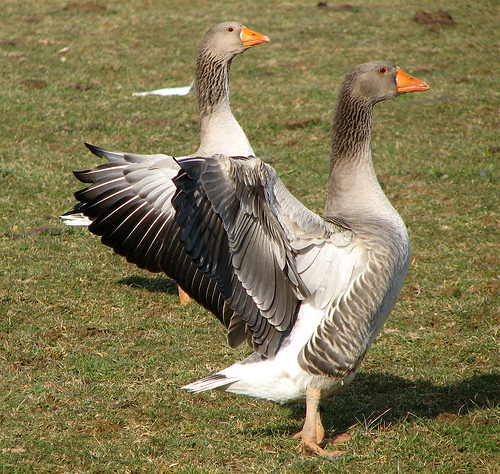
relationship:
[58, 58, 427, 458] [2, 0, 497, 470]
bird in grass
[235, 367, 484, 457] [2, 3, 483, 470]
shadow on ground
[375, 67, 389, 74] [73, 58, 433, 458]
eye of goose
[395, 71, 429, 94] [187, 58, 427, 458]
beak of bird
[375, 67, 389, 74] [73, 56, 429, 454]
eye of bird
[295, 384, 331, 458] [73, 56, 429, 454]
leg of bird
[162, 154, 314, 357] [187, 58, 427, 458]
wing of bird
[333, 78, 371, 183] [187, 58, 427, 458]
neck of bird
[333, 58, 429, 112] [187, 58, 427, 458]
head of bird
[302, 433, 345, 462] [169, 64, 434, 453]
claw of bird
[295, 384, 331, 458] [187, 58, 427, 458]
leg of bird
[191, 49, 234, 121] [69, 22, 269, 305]
neck of bird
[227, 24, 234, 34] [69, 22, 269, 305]
eye of bird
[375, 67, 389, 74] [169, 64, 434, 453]
eye of bird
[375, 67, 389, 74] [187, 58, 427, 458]
eye of bird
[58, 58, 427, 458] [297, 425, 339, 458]
bird has foot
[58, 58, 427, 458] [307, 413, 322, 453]
bird has foot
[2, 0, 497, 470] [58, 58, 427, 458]
grass by bird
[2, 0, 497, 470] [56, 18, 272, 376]
grass by goose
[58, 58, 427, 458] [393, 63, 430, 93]
bird has beak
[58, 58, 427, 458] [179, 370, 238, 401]
bird has tail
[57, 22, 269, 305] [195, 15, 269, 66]
bird has head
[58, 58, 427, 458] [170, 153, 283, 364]
bird has wing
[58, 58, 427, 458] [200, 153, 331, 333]
bird has wing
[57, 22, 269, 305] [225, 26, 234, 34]
bird has eye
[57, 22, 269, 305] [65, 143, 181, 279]
bird has feathers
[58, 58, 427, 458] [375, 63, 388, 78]
bird has eye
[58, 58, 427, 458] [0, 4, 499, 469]
bird on lawn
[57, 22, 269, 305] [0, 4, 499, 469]
bird on lawn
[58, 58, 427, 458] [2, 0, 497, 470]
bird standing on grass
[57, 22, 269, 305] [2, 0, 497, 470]
bird standing on grass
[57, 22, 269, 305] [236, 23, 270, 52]
bird has beak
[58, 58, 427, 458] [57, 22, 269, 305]
bird standing by bird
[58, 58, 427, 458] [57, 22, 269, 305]
bird standing next to bird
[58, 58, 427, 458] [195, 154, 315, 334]
bird has wing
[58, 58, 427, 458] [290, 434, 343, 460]
bird has foot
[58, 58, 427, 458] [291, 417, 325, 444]
bird has foot